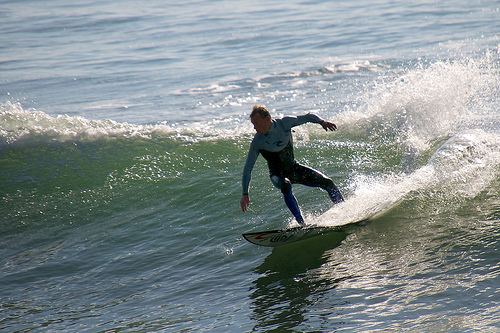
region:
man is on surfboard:
[201, 80, 332, 238]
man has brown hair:
[242, 94, 270, 122]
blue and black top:
[262, 114, 289, 171]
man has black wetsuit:
[260, 171, 344, 248]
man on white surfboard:
[245, 217, 356, 244]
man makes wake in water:
[301, 155, 449, 237]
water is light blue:
[14, 160, 249, 327]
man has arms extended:
[227, 107, 361, 218]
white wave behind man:
[2, 93, 399, 144]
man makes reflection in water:
[231, 217, 331, 329]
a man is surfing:
[214, 86, 428, 278]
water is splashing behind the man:
[344, 48, 490, 219]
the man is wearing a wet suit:
[238, 110, 340, 222]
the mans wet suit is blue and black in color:
[238, 105, 358, 222]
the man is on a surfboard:
[231, 172, 416, 259]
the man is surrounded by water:
[71, 40, 471, 302]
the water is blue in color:
[23, 8, 460, 75]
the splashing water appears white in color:
[393, 78, 488, 185]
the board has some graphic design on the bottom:
[237, 213, 423, 254]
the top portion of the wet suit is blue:
[223, 115, 333, 178]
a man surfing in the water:
[199, 61, 392, 265]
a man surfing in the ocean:
[221, 97, 363, 259]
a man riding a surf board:
[205, 103, 365, 255]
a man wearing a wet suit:
[247, 73, 370, 228]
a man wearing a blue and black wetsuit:
[243, 98, 325, 218]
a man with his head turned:
[233, 101, 286, 145]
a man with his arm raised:
[260, 71, 345, 221]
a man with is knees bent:
[240, 81, 334, 231]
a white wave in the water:
[366, 73, 470, 227]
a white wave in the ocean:
[383, 72, 463, 230]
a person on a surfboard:
[179, 73, 425, 287]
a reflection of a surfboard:
[226, 228, 338, 332]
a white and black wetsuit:
[211, 88, 368, 246]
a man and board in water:
[218, 78, 397, 277]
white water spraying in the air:
[306, 61, 491, 245]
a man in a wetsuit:
[213, 87, 401, 272]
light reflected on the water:
[354, 218, 474, 330]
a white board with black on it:
[236, 224, 376, 254]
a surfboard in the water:
[229, 211, 421, 264]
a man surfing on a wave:
[181, 74, 415, 284]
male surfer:
[218, 99, 391, 257]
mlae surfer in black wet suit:
[223, 97, 344, 240]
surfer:
[205, 89, 345, 245]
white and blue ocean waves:
[32, 10, 107, 68]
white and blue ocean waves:
[53, 128, 98, 178]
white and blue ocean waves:
[112, 47, 188, 108]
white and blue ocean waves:
[354, 29, 405, 59]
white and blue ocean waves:
[79, 213, 144, 251]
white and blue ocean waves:
[82, 31, 134, 96]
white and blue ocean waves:
[43, 36, 102, 101]